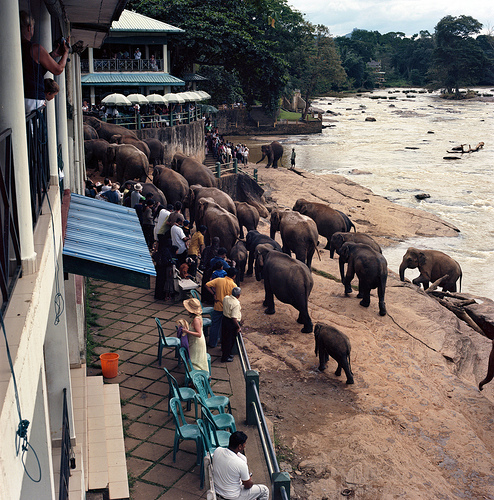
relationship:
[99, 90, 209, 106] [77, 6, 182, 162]
umbrellas outside building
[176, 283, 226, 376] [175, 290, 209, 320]
woman wearing hat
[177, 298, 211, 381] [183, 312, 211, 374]
woman wearing dress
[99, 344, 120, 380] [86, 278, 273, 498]
bucket on sidewalk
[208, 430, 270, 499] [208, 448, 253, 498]
man wearing shirt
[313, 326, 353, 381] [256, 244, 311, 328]
elephant behind elephant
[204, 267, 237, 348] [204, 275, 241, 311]
man wearing shirt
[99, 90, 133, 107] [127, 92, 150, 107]
umbrella next to umbrella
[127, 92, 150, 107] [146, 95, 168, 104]
umbrella next to umbrella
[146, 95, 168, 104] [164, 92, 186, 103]
umbrella next to umbrella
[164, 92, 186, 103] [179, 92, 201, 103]
umbrella next to umbrella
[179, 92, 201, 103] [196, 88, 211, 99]
umbrella next to umbrella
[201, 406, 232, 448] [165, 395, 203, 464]
chair next to chair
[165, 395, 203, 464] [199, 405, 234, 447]
chair next to chair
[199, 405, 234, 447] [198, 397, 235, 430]
chair next to chair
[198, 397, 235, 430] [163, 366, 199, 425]
chair next to chair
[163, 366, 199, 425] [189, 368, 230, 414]
chair next to chair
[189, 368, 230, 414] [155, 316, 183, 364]
chair next to chair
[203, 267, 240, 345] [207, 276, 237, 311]
man wearing shirt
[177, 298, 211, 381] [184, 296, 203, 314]
woman wearing hat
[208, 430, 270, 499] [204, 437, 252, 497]
man wearing shirt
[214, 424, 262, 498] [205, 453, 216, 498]
man sitting in chair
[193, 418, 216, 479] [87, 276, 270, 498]
chair on deck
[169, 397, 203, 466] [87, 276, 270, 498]
chair on deck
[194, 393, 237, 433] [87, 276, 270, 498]
chair on deck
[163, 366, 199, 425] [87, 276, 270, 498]
chair on deck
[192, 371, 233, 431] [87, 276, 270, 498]
chair on deck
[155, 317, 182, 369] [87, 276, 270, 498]
blue chairs on deck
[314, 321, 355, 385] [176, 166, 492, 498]
elephant walking on rocks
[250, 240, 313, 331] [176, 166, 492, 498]
elephant walking on rocks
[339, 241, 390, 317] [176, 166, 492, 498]
elephant walking on rocks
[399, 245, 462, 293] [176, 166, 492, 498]
elephant walking on rocks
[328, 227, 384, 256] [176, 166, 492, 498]
elephant walking on rocks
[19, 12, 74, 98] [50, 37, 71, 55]
person taking photo with camera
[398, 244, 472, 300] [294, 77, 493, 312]
elephant stepping out of river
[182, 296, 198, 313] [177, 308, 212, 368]
hat and a dress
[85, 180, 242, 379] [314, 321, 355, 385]
people are watching elephant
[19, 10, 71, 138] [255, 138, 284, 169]
person recording elephant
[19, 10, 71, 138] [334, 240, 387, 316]
person recording elephant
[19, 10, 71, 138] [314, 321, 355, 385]
person recording elephant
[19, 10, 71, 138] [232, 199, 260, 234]
person recording elephant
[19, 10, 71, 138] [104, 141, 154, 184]
person recording elephant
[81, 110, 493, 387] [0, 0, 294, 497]
elephants moving through a town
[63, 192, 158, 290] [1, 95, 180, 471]
awning of a building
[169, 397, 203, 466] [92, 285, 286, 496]
chair on a patio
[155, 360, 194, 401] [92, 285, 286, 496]
chair on a patio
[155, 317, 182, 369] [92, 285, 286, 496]
blue chairs on a patio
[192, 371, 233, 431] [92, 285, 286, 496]
chair on a patio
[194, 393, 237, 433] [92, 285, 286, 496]
chair on a patio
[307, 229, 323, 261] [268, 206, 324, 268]
tail of an elephant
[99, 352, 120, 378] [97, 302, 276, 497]
bucket of on a patio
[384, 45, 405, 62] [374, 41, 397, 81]
leaves of a tree